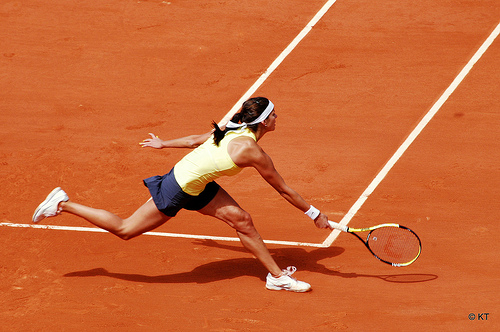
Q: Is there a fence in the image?
A: No, there are no fences.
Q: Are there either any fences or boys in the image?
A: No, there are no fences or boys.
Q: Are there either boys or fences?
A: No, there are no fences or boys.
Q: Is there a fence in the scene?
A: No, there are no fences.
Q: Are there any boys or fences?
A: No, there are no fences or boys.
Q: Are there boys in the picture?
A: No, there are no boys.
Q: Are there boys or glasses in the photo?
A: No, there are no boys or glasses.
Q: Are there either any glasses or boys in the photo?
A: No, there are no boys or glasses.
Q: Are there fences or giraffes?
A: No, there are no fences or giraffes.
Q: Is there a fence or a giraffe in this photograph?
A: No, there are no fences or giraffes.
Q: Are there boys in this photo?
A: No, there are no boys.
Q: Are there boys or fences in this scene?
A: No, there are no boys or fences.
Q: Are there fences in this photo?
A: No, there are no fences.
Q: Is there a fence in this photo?
A: No, there are no fences.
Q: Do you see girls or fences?
A: No, there are no fences or girls.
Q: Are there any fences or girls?
A: No, there are no fences or girls.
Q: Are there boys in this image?
A: No, there are no boys.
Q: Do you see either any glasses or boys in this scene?
A: No, there are no boys or glasses.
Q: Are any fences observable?
A: No, there are no fences.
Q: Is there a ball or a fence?
A: No, there are no fences or balls.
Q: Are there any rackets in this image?
A: Yes, there is a racket.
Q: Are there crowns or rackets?
A: Yes, there is a racket.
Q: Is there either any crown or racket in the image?
A: Yes, there is a racket.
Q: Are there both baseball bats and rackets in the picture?
A: No, there is a racket but no baseball bats.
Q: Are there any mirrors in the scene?
A: No, there are no mirrors.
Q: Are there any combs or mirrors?
A: No, there are no mirrors or combs.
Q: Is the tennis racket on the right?
A: Yes, the tennis racket is on the right of the image.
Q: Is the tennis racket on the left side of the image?
A: No, the tennis racket is on the right of the image.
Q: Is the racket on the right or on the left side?
A: The racket is on the right of the image.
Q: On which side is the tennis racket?
A: The tennis racket is on the right of the image.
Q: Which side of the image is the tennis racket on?
A: The tennis racket is on the right of the image.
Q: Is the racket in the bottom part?
A: Yes, the racket is in the bottom of the image.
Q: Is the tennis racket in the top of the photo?
A: No, the tennis racket is in the bottom of the image.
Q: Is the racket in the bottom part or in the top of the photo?
A: The racket is in the bottom of the image.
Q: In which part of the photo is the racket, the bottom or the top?
A: The racket is in the bottom of the image.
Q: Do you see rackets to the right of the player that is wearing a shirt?
A: Yes, there is a racket to the right of the player.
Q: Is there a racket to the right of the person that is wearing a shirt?
A: Yes, there is a racket to the right of the player.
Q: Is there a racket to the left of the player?
A: No, the racket is to the right of the player.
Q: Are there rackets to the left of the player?
A: No, the racket is to the right of the player.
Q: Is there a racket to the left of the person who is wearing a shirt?
A: No, the racket is to the right of the player.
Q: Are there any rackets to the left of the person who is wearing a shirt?
A: No, the racket is to the right of the player.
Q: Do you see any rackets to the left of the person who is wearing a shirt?
A: No, the racket is to the right of the player.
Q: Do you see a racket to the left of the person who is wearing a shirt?
A: No, the racket is to the right of the player.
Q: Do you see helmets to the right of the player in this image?
A: No, there is a racket to the right of the player.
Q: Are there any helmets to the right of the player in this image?
A: No, there is a racket to the right of the player.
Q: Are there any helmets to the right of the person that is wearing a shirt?
A: No, there is a racket to the right of the player.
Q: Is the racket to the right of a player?
A: Yes, the racket is to the right of a player.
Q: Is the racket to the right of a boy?
A: No, the racket is to the right of a player.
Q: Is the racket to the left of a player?
A: No, the racket is to the right of a player.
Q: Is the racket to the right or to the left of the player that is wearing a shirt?
A: The racket is to the right of the player.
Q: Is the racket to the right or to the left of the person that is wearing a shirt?
A: The racket is to the right of the player.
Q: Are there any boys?
A: No, there are no boys.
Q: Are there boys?
A: No, there are no boys.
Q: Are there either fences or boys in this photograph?
A: No, there are no boys or fences.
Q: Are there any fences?
A: No, there are no fences.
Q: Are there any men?
A: No, there are no men.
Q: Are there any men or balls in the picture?
A: No, there are no men or balls.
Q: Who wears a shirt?
A: The player wears a shirt.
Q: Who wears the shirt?
A: The player wears a shirt.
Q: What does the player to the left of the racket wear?
A: The player wears a shirt.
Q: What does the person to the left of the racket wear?
A: The player wears a shirt.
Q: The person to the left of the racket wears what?
A: The player wears a shirt.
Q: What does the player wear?
A: The player wears a shirt.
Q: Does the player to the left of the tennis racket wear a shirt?
A: Yes, the player wears a shirt.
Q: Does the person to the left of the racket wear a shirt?
A: Yes, the player wears a shirt.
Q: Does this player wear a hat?
A: No, the player wears a shirt.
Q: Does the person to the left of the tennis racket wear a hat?
A: No, the player wears a shirt.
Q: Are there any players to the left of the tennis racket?
A: Yes, there is a player to the left of the tennis racket.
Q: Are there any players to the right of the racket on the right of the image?
A: No, the player is to the left of the racket.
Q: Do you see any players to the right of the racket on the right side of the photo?
A: No, the player is to the left of the racket.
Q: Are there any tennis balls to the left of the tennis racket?
A: No, there is a player to the left of the tennis racket.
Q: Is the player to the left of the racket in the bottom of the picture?
A: Yes, the player is to the left of the racket.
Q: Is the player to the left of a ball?
A: No, the player is to the left of the racket.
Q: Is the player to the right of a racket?
A: No, the player is to the left of a racket.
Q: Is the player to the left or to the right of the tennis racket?
A: The player is to the left of the tennis racket.